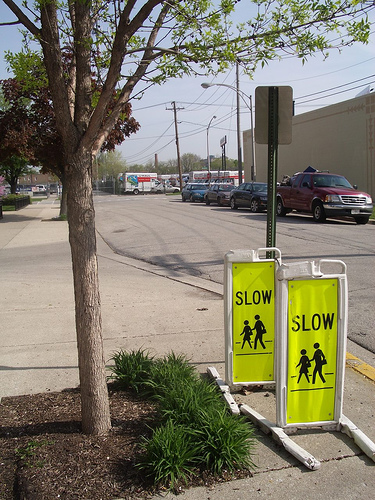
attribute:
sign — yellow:
[223, 244, 284, 391]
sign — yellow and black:
[219, 230, 359, 449]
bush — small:
[110, 349, 157, 391]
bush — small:
[156, 350, 196, 396]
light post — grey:
[201, 78, 259, 185]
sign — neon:
[217, 239, 286, 392]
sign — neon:
[261, 256, 354, 431]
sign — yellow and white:
[278, 255, 352, 430]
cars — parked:
[272, 169, 373, 225]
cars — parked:
[226, 183, 276, 214]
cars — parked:
[201, 182, 238, 206]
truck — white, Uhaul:
[122, 163, 170, 193]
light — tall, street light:
[196, 77, 255, 113]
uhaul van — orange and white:
[118, 172, 159, 193]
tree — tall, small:
[1, 1, 186, 437]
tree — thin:
[0, 0, 373, 435]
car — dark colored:
[228, 177, 270, 211]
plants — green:
[109, 346, 252, 493]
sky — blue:
[158, 63, 228, 127]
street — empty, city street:
[99, 162, 363, 442]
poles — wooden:
[141, 101, 213, 179]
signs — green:
[219, 243, 361, 455]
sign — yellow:
[286, 278, 338, 424]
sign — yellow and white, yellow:
[232, 262, 275, 383]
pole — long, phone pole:
[165, 102, 196, 200]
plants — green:
[143, 5, 275, 53]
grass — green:
[142, 367, 214, 470]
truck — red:
[275, 168, 373, 229]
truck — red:
[276, 167, 370, 223]